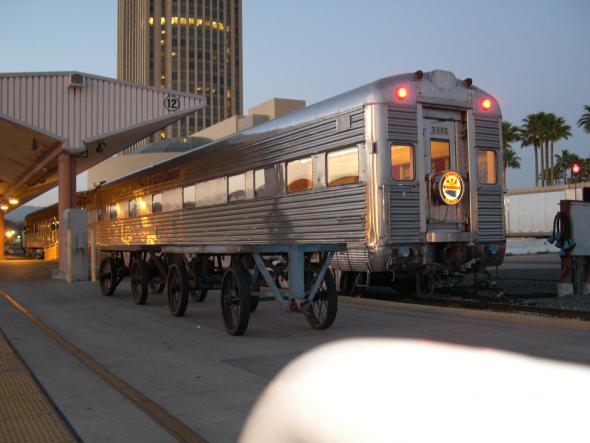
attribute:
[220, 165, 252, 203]
window — glass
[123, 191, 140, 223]
window — glass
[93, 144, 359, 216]
window — glass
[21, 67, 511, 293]
train — silver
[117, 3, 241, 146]
building — tall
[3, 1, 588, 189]
sky — blue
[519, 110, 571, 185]
palm tree — tall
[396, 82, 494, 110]
lights — red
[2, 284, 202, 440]
line — yellow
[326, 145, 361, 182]
window — reflecting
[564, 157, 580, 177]
light — red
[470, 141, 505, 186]
window — back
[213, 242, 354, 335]
wheels — back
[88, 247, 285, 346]
wheels — left side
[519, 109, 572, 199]
palm tree — tall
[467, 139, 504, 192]
window — glass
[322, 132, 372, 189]
window — glass